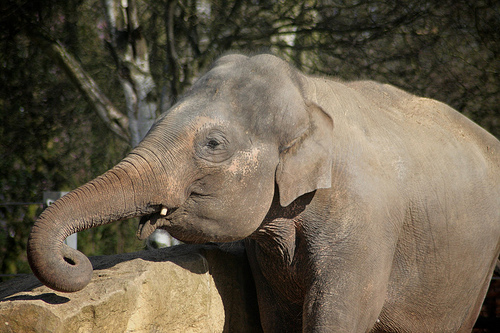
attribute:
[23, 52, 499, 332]
elephant — gray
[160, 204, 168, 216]
tusk — white, ivory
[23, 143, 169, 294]
trunk — curled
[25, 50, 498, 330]
skin — wrinkled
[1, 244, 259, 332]
wall — stone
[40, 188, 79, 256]
pole — grey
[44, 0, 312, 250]
trees — high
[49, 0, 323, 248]
bark — white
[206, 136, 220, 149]
eyes — black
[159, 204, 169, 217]
tusk — white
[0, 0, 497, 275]
building — hidden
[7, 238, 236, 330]
wall — syone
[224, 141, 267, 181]
marks — white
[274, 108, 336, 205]
ear — gray, small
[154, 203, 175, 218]
tusk — small, white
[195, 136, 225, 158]
eye — black, small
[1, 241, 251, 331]
rock — large